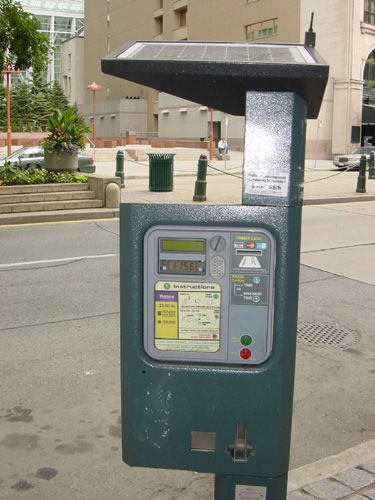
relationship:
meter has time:
[97, 40, 333, 500] [164, 261, 198, 272]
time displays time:
[164, 261, 198, 272] [164, 261, 198, 272]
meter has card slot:
[97, 40, 333, 500] [236, 249, 261, 258]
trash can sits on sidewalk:
[146, 153, 176, 195] [120, 171, 374, 204]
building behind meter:
[84, 3, 374, 159] [97, 40, 333, 500]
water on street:
[9, 407, 121, 496] [3, 207, 370, 443]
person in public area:
[217, 137, 229, 155] [90, 140, 244, 174]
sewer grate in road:
[295, 322, 355, 351] [3, 207, 370, 443]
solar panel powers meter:
[115, 46, 312, 61] [97, 40, 333, 500]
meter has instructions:
[97, 40, 333, 500] [153, 281, 218, 354]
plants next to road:
[45, 113, 82, 153] [3, 207, 370, 443]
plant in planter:
[45, 113, 82, 153] [44, 146, 80, 172]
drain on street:
[295, 322, 355, 351] [3, 207, 370, 443]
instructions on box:
[153, 281, 218, 354] [97, 40, 333, 500]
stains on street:
[9, 407, 121, 496] [3, 207, 370, 443]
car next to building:
[334, 146, 374, 170] [84, 3, 374, 159]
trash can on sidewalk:
[146, 153, 176, 195] [120, 171, 374, 204]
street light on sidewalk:
[89, 82, 101, 148] [120, 171, 374, 204]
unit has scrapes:
[97, 40, 333, 500] [142, 370, 179, 455]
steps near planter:
[3, 184, 106, 224] [44, 146, 80, 172]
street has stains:
[3, 207, 370, 443] [9, 407, 121, 496]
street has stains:
[3, 207, 370, 443] [345, 349, 373, 378]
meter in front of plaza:
[97, 40, 333, 500] [3, 133, 341, 194]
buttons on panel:
[238, 336, 253, 361] [145, 224, 275, 369]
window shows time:
[158, 257, 207, 278] [164, 261, 198, 272]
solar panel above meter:
[115, 46, 312, 61] [97, 40, 333, 500]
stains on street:
[345, 349, 373, 378] [3, 207, 370, 443]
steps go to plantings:
[3, 184, 106, 224] [5, 139, 93, 185]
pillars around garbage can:
[114, 150, 211, 205] [146, 153, 176, 195]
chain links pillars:
[209, 164, 360, 182] [197, 155, 372, 197]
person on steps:
[217, 137, 229, 155] [123, 148, 228, 162]